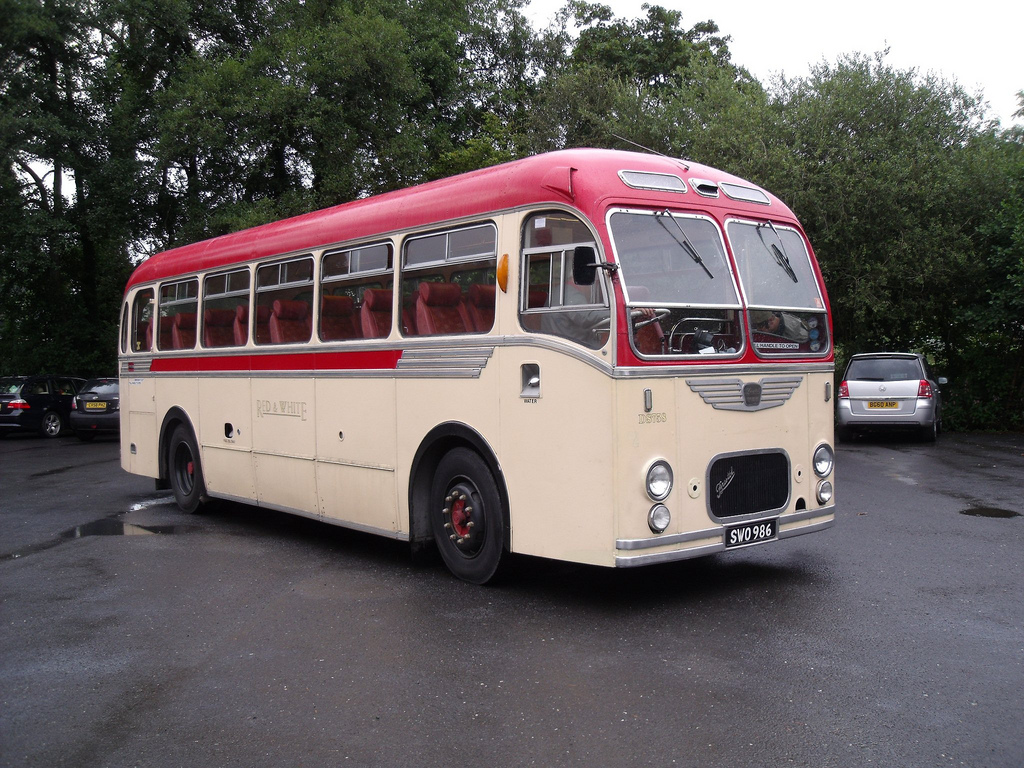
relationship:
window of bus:
[605, 207, 747, 360] [111, 130, 840, 591]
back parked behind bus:
[836, 352, 948, 443] [111, 130, 840, 591]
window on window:
[605, 207, 747, 360] [603, 208, 746, 358]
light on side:
[491, 245, 511, 300] [113, 141, 617, 591]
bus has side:
[111, 130, 840, 591] [113, 141, 617, 591]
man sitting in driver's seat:
[536, 256, 655, 352] [523, 281, 556, 340]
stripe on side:
[143, 346, 409, 375] [113, 141, 617, 591]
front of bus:
[562, 145, 843, 576] [111, 130, 840, 591]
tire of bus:
[424, 443, 511, 591] [111, 130, 840, 591]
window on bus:
[512, 206, 614, 354] [111, 130, 840, 591]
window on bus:
[603, 208, 746, 358] [111, 130, 840, 591]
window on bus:
[722, 219, 831, 358] [111, 130, 840, 591]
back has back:
[836, 352, 948, 443] [834, 348, 934, 435]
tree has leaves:
[147, 9, 470, 215] [143, 7, 474, 170]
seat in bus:
[409, 275, 483, 343] [111, 130, 840, 591]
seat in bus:
[459, 281, 496, 334] [111, 130, 840, 591]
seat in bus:
[357, 282, 424, 343] [111, 130, 840, 591]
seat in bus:
[314, 292, 366, 344] [111, 130, 840, 591]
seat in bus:
[264, 297, 314, 347] [111, 130, 840, 591]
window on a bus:
[723, 217, 832, 358] [111, 130, 840, 591]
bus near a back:
[111, 130, 840, 591] [836, 352, 948, 443]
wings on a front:
[679, 357, 807, 418] [606, 152, 838, 565]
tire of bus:
[163, 417, 202, 510] [111, 130, 840, 591]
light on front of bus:
[640, 458, 679, 534] [111, 130, 840, 591]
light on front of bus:
[811, 437, 838, 502] [111, 130, 840, 591]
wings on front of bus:
[496, 299, 602, 464] [105, 117, 903, 697]